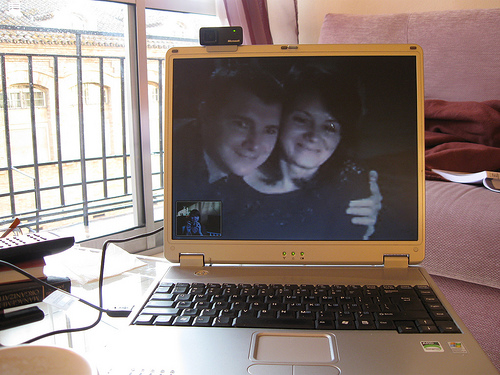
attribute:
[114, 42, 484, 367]
laptop — silver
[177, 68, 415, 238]
couple — smiling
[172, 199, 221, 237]
photo — smaller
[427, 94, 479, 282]
area — sleeping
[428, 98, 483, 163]
bedding — rumpled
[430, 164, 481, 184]
book — open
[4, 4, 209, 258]
window — uncovered, silver-framed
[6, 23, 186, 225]
fencing — black, terrace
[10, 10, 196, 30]
tiling — curved, red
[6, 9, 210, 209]
building — sand-colored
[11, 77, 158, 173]
windows — arched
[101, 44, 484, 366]
computer — open, laptop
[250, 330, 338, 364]
pad — computer, track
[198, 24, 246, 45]
cam — black, net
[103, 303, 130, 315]
plug — black, usb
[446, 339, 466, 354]
logo — microsoft, windows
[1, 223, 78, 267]
control — black, remote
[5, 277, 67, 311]
book — black, hardback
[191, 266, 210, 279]
button — laptop, power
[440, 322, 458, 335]
key — arrow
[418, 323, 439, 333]
key — arrow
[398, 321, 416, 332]
key — arrow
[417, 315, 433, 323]
key — arrow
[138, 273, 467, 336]
keyboard — black, computer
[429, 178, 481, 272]
couch — pink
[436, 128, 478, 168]
blanket — red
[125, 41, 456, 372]
laptop — silver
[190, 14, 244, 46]
camera — black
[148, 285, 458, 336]
keyboard — black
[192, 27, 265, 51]
camera — black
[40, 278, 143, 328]
cable — black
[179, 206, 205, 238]
girl — little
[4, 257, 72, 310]
books — stacked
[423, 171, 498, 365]
sofa — pink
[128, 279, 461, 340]
keys — black